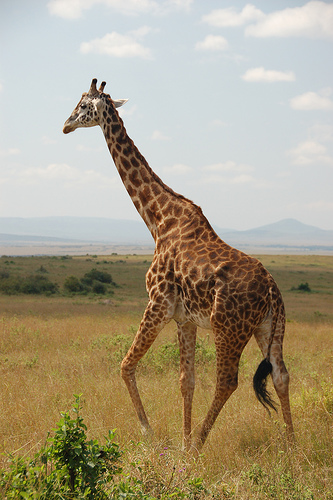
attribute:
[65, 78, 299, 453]
giraffe — tall, walking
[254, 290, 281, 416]
tail — thin, swinging, long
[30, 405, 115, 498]
plant — green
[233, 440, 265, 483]
grass — brown, dried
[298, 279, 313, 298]
bush — green, far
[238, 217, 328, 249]
mountain — blurry, distant, tall, far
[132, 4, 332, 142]
sky — cloudy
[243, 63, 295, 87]
cloud — white, high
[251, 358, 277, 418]
hair — long, black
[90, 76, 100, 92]
horn — short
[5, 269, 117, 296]
bushes — green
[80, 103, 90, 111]
eye — small, black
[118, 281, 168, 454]
leg — bent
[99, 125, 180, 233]
neck — bumpy, long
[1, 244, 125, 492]
field — large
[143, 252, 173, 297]
shoulder — angled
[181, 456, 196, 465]
hoove — hidden